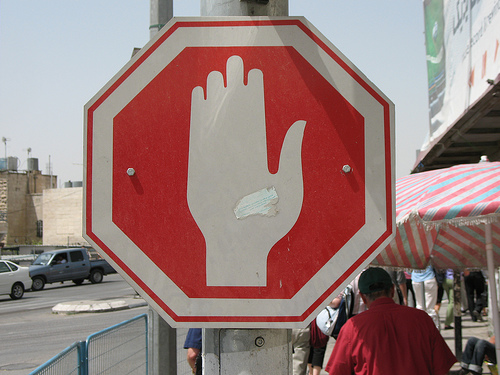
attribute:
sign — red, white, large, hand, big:
[121, 68, 378, 298]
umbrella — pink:
[433, 187, 472, 240]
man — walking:
[351, 259, 425, 343]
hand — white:
[182, 74, 317, 239]